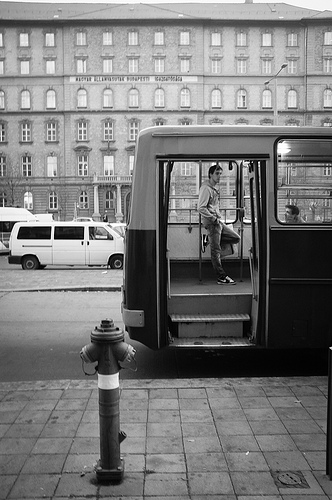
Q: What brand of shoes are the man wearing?
A: Nike.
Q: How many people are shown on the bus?
A: Two.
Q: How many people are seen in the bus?
A: 2.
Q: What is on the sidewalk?
A: Fire Hydrant.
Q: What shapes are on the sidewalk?
A: Squares.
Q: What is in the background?
A: A warehouse building.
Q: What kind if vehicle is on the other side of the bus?
A: Passenger van.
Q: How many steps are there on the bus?
A: 2.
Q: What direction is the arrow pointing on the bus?
A: To the right.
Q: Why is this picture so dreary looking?
A: It's in black and white.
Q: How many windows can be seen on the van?
A: 3.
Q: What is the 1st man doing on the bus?
A: Standing.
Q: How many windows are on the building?
A: There are more than 50.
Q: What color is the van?
A: It is white.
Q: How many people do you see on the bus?
A: 2.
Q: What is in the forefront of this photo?
A: A fire hydrant.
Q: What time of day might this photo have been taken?
A: In the afternoon.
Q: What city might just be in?
A: Rome.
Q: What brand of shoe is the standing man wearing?
A: Nike.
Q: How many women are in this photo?
A: None.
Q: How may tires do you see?
A: 2.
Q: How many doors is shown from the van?
A: It shows two.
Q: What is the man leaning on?
A: A pole.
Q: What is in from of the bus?
A: A hydrant.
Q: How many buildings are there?
A: One.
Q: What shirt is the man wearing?
A: A sweatshirt.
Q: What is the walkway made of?
A: Made of cement.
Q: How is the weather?
A: Overcast.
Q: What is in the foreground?
A: A fire hydrant.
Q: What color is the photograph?
A: Black and white.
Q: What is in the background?
A: A building.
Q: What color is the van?
A: White.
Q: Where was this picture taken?
A: In the city.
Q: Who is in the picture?
A: A man.